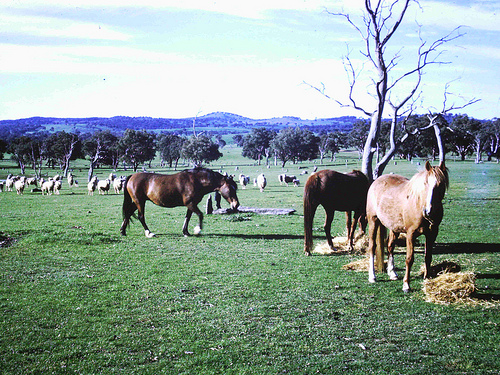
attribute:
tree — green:
[188, 136, 220, 167]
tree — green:
[159, 135, 186, 168]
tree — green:
[123, 131, 155, 170]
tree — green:
[86, 134, 122, 171]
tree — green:
[52, 130, 80, 177]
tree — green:
[273, 130, 298, 168]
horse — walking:
[126, 167, 239, 236]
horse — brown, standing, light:
[366, 160, 448, 293]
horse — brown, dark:
[303, 168, 375, 255]